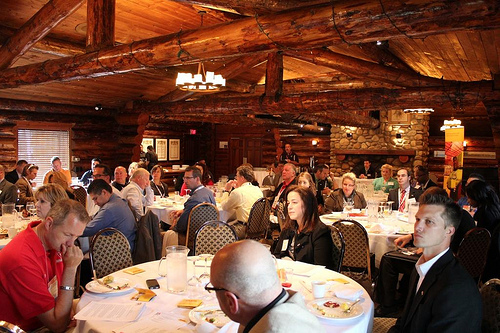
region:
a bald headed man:
[196, 234, 315, 331]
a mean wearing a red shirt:
[5, 198, 90, 323]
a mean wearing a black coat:
[393, 194, 473, 329]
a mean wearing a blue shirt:
[80, 175, 134, 240]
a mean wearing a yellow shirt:
[222, 166, 267, 228]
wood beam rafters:
[2, 7, 494, 123]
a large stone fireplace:
[323, 105, 427, 177]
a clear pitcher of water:
[157, 242, 192, 294]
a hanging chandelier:
[173, 58, 231, 97]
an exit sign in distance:
[182, 124, 198, 139]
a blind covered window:
[15, 125, 72, 192]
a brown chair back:
[85, 225, 133, 276]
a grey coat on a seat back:
[135, 208, 161, 258]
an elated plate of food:
[301, 291, 367, 321]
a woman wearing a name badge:
[271, 180, 335, 265]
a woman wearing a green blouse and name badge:
[371, 165, 397, 191]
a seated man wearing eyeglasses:
[175, 166, 218, 230]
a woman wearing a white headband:
[16, 160, 41, 199]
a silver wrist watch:
[56, 282, 78, 294]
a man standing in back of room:
[276, 141, 300, 166]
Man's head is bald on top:
[210, 240, 280, 304]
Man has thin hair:
[218, 261, 283, 301]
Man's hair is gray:
[216, 264, 288, 296]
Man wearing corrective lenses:
[203, 274, 240, 302]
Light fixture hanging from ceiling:
[164, 48, 230, 98]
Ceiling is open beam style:
[58, 15, 413, 137]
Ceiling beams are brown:
[34, 12, 457, 112]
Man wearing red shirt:
[2, 199, 79, 329]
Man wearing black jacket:
[398, 189, 476, 326]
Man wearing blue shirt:
[88, 177, 140, 250]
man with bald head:
[206, 234, 302, 330]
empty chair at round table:
[190, 215, 240, 266]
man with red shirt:
[3, 223, 90, 331]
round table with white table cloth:
[91, 240, 361, 323]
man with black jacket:
[394, 251, 477, 330]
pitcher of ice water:
[153, 240, 195, 298]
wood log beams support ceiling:
[46, 18, 379, 50]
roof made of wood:
[69, 9, 321, 146]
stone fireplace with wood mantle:
[321, 112, 436, 192]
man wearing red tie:
[380, 156, 422, 219]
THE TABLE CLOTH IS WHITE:
[177, 325, 184, 332]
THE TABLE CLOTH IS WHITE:
[159, 277, 164, 310]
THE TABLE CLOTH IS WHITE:
[179, 291, 189, 315]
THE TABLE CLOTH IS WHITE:
[176, 302, 184, 328]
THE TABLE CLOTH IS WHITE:
[163, 305, 180, 315]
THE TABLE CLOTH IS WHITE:
[177, 320, 189, 325]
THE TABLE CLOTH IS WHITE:
[163, 315, 178, 322]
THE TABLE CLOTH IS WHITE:
[153, 318, 163, 324]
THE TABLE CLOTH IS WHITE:
[179, 329, 182, 331]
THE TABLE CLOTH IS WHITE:
[158, 303, 170, 314]